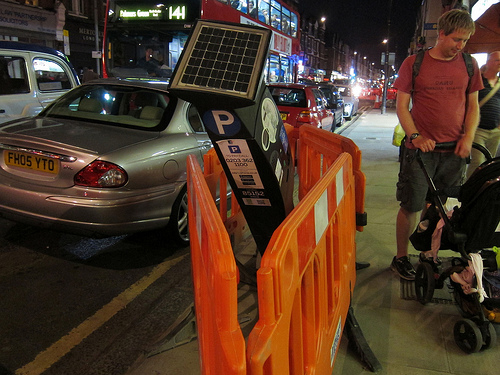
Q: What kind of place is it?
A: It is a street.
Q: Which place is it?
A: It is a street.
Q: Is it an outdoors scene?
A: Yes, it is outdoors.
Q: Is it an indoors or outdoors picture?
A: It is outdoors.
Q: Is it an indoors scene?
A: No, it is outdoors.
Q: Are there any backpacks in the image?
A: Yes, there is a backpack.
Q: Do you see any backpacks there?
A: Yes, there is a backpack.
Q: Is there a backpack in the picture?
A: Yes, there is a backpack.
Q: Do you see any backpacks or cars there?
A: Yes, there is a backpack.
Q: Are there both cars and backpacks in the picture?
A: Yes, there are both a backpack and a car.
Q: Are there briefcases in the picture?
A: No, there are no briefcases.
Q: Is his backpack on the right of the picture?
A: Yes, the backpack is on the right of the image.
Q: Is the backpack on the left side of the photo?
A: No, the backpack is on the right of the image.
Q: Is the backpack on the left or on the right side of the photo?
A: The backpack is on the right of the image.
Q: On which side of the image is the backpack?
A: The backpack is on the right of the image.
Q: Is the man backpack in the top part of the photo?
A: Yes, the backpack is in the top of the image.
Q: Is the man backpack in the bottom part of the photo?
A: No, the backpack is in the top of the image.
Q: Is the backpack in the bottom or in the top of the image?
A: The backpack is in the top of the image.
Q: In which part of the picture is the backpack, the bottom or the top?
A: The backpack is in the top of the image.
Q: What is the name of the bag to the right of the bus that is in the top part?
A: The bag is a backpack.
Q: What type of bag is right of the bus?
A: The bag is a backpack.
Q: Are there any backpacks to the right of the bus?
A: Yes, there is a backpack to the right of the bus.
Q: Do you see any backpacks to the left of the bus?
A: No, the backpack is to the right of the bus.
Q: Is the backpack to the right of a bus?
A: Yes, the backpack is to the right of a bus.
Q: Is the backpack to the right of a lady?
A: No, the backpack is to the right of a bus.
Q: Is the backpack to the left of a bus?
A: No, the backpack is to the right of a bus.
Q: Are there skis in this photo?
A: No, there are no skis.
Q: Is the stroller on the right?
A: Yes, the stroller is on the right of the image.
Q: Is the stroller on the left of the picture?
A: No, the stroller is on the right of the image.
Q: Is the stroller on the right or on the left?
A: The stroller is on the right of the image.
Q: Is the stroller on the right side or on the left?
A: The stroller is on the right of the image.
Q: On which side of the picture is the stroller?
A: The stroller is on the right of the image.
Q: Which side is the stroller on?
A: The stroller is on the right of the image.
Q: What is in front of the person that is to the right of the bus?
A: The stroller is in front of the man.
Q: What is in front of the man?
A: The stroller is in front of the man.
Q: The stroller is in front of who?
A: The stroller is in front of the man.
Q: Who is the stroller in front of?
A: The stroller is in front of the man.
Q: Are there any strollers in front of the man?
A: Yes, there is a stroller in front of the man.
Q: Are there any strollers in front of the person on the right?
A: Yes, there is a stroller in front of the man.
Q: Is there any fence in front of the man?
A: No, there is a stroller in front of the man.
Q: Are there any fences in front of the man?
A: No, there is a stroller in front of the man.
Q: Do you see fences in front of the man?
A: No, there is a stroller in front of the man.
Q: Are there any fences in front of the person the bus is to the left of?
A: No, there is a stroller in front of the man.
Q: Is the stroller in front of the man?
A: Yes, the stroller is in front of the man.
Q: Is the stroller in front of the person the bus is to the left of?
A: Yes, the stroller is in front of the man.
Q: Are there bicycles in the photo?
A: No, there are no bicycles.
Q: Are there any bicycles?
A: No, there are no bicycles.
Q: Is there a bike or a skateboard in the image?
A: No, there are no bikes or skateboards.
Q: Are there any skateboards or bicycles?
A: No, there are no bicycles or skateboards.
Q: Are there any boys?
A: No, there are no boys.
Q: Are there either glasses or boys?
A: No, there are no boys or glasses.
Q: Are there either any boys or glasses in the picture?
A: No, there are no boys or glasses.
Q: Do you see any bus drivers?
A: No, there are no bus drivers.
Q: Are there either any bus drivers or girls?
A: No, there are no bus drivers or girls.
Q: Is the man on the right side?
A: Yes, the man is on the right of the image.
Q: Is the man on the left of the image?
A: No, the man is on the right of the image.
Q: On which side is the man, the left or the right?
A: The man is on the right of the image.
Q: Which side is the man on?
A: The man is on the right of the image.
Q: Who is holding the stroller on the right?
A: The man is holding the stroller.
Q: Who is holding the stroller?
A: The man is holding the stroller.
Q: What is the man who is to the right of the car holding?
A: The man is holding the stroller.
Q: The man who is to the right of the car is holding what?
A: The man is holding the stroller.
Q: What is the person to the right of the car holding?
A: The man is holding the stroller.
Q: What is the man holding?
A: The man is holding the stroller.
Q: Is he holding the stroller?
A: Yes, the man is holding the stroller.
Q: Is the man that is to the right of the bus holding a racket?
A: No, the man is holding the stroller.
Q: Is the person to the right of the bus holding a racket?
A: No, the man is holding the stroller.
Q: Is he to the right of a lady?
A: No, the man is to the right of the car.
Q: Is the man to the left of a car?
A: No, the man is to the right of a car.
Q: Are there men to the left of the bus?
A: No, the man is to the right of the bus.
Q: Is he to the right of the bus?
A: Yes, the man is to the right of the bus.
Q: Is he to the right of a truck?
A: No, the man is to the right of the bus.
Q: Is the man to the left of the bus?
A: No, the man is to the right of the bus.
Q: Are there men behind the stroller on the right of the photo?
A: Yes, there is a man behind the stroller.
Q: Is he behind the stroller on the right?
A: Yes, the man is behind the stroller.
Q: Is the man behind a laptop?
A: No, the man is behind the stroller.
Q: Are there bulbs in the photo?
A: No, there are no bulbs.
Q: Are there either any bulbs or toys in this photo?
A: No, there are no bulbs or toys.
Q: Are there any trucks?
A: No, there are no trucks.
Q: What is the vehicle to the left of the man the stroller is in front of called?
A: The vehicle is a car.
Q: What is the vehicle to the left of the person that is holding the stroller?
A: The vehicle is a car.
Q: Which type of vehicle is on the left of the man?
A: The vehicle is a car.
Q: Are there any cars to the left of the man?
A: Yes, there is a car to the left of the man.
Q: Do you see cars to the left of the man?
A: Yes, there is a car to the left of the man.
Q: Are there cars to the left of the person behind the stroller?
A: Yes, there is a car to the left of the man.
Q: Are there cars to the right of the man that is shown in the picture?
A: No, the car is to the left of the man.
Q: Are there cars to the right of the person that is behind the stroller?
A: No, the car is to the left of the man.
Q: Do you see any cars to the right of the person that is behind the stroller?
A: No, the car is to the left of the man.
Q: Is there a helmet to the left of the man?
A: No, there is a car to the left of the man.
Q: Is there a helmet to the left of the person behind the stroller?
A: No, there is a car to the left of the man.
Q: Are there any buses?
A: Yes, there is a bus.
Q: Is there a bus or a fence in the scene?
A: Yes, there is a bus.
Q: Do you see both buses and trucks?
A: No, there is a bus but no trucks.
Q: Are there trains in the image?
A: No, there are no trains.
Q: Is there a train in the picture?
A: No, there are no trains.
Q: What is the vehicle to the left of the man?
A: The vehicle is a bus.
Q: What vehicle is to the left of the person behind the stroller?
A: The vehicle is a bus.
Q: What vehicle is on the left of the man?
A: The vehicle is a bus.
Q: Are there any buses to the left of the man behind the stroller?
A: Yes, there is a bus to the left of the man.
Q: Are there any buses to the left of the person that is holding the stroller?
A: Yes, there is a bus to the left of the man.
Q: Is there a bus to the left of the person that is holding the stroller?
A: Yes, there is a bus to the left of the man.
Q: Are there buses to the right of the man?
A: No, the bus is to the left of the man.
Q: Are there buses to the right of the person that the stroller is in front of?
A: No, the bus is to the left of the man.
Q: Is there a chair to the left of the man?
A: No, there is a bus to the left of the man.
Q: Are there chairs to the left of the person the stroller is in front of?
A: No, there is a bus to the left of the man.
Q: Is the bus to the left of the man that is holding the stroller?
A: Yes, the bus is to the left of the man.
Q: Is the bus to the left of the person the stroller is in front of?
A: Yes, the bus is to the left of the man.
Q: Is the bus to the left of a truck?
A: No, the bus is to the left of the man.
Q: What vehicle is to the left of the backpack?
A: The vehicle is a bus.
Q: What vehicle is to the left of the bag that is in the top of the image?
A: The vehicle is a bus.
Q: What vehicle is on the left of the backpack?
A: The vehicle is a bus.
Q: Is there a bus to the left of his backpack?
A: Yes, there is a bus to the left of the backpack.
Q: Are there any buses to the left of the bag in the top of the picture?
A: Yes, there is a bus to the left of the backpack.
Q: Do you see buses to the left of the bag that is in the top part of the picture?
A: Yes, there is a bus to the left of the backpack.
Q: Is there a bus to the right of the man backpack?
A: No, the bus is to the left of the backpack.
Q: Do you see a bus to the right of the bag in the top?
A: No, the bus is to the left of the backpack.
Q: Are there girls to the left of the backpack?
A: No, there is a bus to the left of the backpack.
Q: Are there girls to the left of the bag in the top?
A: No, there is a bus to the left of the backpack.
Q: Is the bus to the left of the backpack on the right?
A: Yes, the bus is to the left of the backpack.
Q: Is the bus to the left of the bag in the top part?
A: Yes, the bus is to the left of the backpack.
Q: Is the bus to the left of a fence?
A: No, the bus is to the left of the backpack.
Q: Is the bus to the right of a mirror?
A: No, the bus is to the right of the car.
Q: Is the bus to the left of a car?
A: No, the bus is to the right of a car.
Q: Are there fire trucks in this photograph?
A: No, there are no fire trucks.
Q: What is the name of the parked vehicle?
A: The vehicle is a car.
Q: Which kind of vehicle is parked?
A: The vehicle is a car.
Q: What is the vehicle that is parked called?
A: The vehicle is a car.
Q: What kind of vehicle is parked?
A: The vehicle is a car.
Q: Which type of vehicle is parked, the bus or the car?
A: The car is parked.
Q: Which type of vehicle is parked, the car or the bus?
A: The car is parked.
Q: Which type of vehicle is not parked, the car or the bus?
A: The bus is not parked.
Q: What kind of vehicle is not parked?
A: The vehicle is a bus.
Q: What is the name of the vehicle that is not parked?
A: The vehicle is a bus.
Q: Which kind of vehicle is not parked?
A: The vehicle is a bus.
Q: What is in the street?
A: The car is in the street.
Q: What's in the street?
A: The car is in the street.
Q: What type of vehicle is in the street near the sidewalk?
A: The vehicle is a car.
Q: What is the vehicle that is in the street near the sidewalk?
A: The vehicle is a car.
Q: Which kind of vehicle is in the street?
A: The vehicle is a car.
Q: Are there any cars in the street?
A: Yes, there is a car in the street.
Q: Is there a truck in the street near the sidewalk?
A: No, there is a car in the street.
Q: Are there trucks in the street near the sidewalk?
A: No, there is a car in the street.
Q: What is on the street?
A: The car is on the street.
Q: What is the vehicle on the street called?
A: The vehicle is a car.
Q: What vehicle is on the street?
A: The vehicle is a car.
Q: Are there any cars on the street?
A: Yes, there is a car on the street.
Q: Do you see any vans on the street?
A: No, there is a car on the street.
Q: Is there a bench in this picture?
A: No, there are no benches.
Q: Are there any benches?
A: No, there are no benches.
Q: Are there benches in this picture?
A: No, there are no benches.